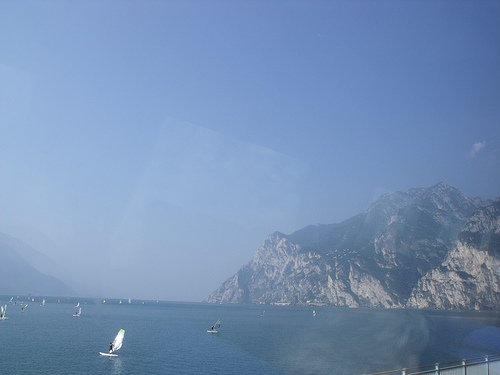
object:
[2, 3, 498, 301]
sky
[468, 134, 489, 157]
clouds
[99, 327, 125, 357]
boat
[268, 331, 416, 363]
water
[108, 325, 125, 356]
sail